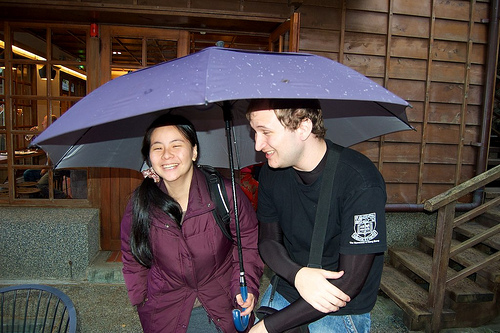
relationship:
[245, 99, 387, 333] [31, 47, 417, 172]
man under umbrella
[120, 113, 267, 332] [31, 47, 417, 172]
woman under umbrella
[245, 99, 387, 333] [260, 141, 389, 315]
man has shirt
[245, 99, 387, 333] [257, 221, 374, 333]
man has arm covers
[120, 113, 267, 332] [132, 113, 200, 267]
woman has hair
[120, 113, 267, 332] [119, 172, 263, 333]
woman has coat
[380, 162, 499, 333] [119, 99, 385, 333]
stairs behind couple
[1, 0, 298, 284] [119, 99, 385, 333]
shop behind couple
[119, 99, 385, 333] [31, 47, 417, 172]
couple under umbrella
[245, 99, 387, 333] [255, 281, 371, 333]
man has pants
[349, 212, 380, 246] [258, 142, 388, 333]
logo on sweater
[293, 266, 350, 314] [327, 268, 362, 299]
hand on elbow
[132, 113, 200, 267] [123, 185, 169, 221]
hair on shoulder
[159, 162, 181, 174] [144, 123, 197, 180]
smile on face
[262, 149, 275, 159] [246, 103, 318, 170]
smile on face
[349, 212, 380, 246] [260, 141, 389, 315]
logo on shirt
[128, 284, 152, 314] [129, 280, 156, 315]
hand in pocket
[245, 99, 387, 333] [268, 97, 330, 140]
man has hair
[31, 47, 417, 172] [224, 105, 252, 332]
umbrella has handle